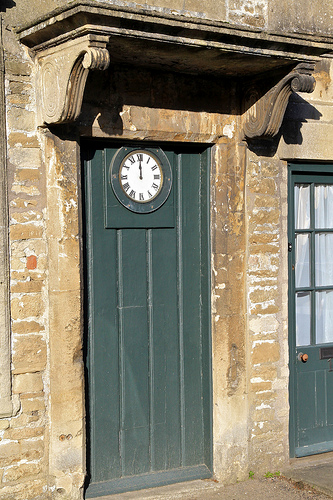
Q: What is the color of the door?
A: Green.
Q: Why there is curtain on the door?
A: To keep too much lights out.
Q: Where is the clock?
A: On the door.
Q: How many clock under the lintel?
A: One.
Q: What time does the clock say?
A: 1200.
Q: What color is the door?
A: Green.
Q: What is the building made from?
A: Bricks.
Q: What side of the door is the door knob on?
A: Left.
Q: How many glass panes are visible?
A: 6.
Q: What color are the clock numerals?
A: Black.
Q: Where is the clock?
A: On the green panel.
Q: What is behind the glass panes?
A: Curtain.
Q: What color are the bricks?
A: Tan.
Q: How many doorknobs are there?
A: 1.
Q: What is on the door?
A: A clock.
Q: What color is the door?
A: Green.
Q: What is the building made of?
A: Brick.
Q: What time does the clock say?
A: 12:00.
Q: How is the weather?
A: Sunny.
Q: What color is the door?
A: Green.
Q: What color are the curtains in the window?
A: White.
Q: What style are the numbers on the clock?
A: Roman.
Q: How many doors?
A: 1.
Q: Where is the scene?
A: Outside a building.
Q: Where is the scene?
A: Outside an old building.